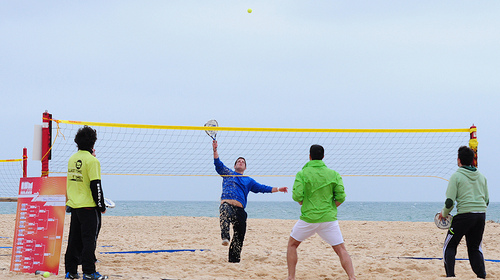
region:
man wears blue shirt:
[213, 153, 250, 206]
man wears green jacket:
[296, 163, 341, 230]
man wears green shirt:
[433, 157, 479, 212]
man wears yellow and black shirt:
[67, 154, 99, 194]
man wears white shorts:
[278, 217, 350, 261]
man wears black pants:
[214, 206, 248, 259]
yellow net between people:
[84, 107, 416, 184]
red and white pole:
[28, 111, 60, 170]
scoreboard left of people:
[15, 163, 67, 264]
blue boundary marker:
[95, 228, 187, 270]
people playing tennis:
[26, 103, 498, 275]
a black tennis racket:
[195, 115, 227, 142]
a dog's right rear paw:
[424, 207, 453, 232]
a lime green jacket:
[293, 156, 344, 219]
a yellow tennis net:
[35, 109, 480, 186]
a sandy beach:
[0, 207, 485, 270]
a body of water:
[6, 194, 490, 217]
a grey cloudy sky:
[0, 2, 490, 200]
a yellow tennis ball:
[244, 7, 254, 14]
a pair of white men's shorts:
[284, 215, 349, 251]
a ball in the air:
[246, 5, 265, 20]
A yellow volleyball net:
[51, 116, 486, 186]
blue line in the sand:
[99, 239, 211, 260]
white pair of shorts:
[287, 209, 354, 254]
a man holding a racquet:
[199, 115, 222, 153]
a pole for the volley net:
[42, 109, 52, 176]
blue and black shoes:
[58, 264, 115, 279]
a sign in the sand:
[3, 169, 70, 279]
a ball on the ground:
[43, 272, 52, 279]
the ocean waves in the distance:
[369, 195, 436, 211]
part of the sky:
[175, 15, 245, 53]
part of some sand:
[181, 254, 203, 269]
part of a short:
[323, 225, 340, 235]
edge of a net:
[366, 173, 399, 198]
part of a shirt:
[310, 182, 328, 203]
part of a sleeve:
[82, 179, 107, 221]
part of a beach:
[195, 249, 215, 259]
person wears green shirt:
[445, 170, 497, 224]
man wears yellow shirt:
[60, 151, 106, 211]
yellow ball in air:
[243, 8, 253, 18]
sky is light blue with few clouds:
[13, 2, 199, 107]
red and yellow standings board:
[10, 167, 61, 275]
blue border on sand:
[75, 231, 195, 261]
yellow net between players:
[61, 107, 487, 193]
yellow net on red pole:
[35, 115, 67, 178]